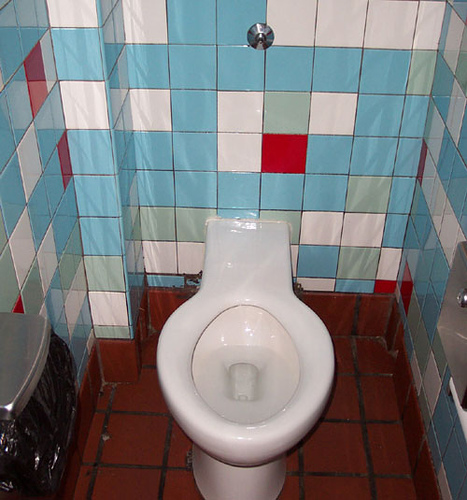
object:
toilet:
[150, 216, 338, 500]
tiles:
[98, 408, 171, 471]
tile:
[261, 133, 308, 176]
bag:
[0, 329, 81, 500]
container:
[434, 241, 467, 411]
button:
[246, 21, 275, 51]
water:
[203, 339, 287, 418]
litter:
[101, 433, 110, 442]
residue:
[184, 277, 202, 297]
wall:
[0, 0, 467, 500]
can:
[0, 311, 53, 423]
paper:
[447, 375, 467, 445]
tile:
[167, 42, 219, 91]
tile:
[262, 89, 312, 135]